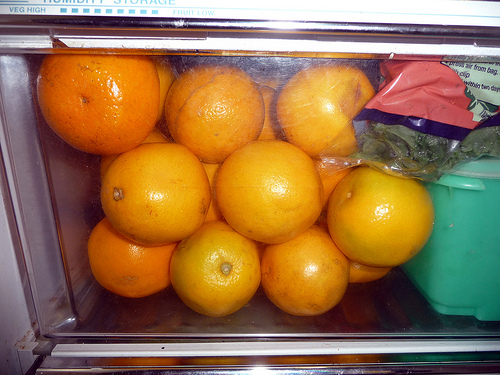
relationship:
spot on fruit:
[75, 88, 95, 112] [38, 53, 156, 149]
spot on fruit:
[71, 90, 97, 110] [34, 51, 163, 154]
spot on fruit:
[77, 99, 94, 111] [34, 51, 163, 154]